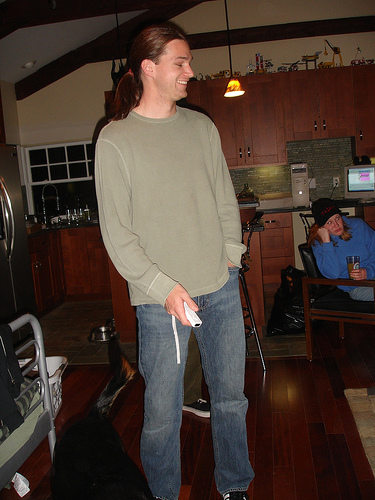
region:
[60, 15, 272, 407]
A man playing Wii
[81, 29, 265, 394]
A man holding a Wii controler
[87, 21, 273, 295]
A man wearing a green shirt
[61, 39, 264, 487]
A man wearing a jeans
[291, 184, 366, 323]
A person sitting in a chair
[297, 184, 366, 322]
A person in a blue shirt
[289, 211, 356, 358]
A person sitting in a black chair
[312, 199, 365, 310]
A person holding a cup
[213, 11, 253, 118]
A light hanging from the ceiling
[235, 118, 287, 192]
brown cabinets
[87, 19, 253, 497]
man holding a white video game controller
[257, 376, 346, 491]
dark hardwood floor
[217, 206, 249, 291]
man's hand in his pocket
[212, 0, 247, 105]
light with a small shade hanging from above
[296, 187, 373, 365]
woman sitting in a chair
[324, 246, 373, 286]
woman resting a drink on chair arm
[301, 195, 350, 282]
woman resting her head on her hand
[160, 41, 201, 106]
man smiling with his eyes closed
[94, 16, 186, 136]
man's brown hair pulled back into a low ponytail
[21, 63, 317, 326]
wooden cabinets and a window in the background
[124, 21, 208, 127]
person smiling with eyes closed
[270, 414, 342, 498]
brown floor beneath man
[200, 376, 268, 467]
long blue pants of man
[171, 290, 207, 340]
remote in man's hand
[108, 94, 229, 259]
long sleeve shirt of man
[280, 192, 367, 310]
woman sitting down in chair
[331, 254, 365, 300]
cup in woman's hand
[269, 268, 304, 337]
black bag behind woman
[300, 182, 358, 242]
black and red hat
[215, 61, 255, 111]
light hanging from ceiling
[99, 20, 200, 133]
person with a ponytail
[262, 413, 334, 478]
reddish brown floor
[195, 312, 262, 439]
blue pants on person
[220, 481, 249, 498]
black and white shoe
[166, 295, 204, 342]
white remote in person's hand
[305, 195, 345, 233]
red and black hat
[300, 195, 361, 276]
girl looking at something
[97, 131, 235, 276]
long sleeve shirt on person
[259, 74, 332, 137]
brown cabinets above ground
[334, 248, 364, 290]
cup in lady's hand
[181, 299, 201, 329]
white video game controller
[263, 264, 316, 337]
black trash bag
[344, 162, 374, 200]
white computer monitor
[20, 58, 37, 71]
kitchen light turned off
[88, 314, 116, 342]
empty dog food dish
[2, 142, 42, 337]
clean stainless steel fridge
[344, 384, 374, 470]
section of tan throw rug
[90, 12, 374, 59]
dark wooden beam across back wall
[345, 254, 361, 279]
clear glass with orange beverage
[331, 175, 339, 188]
outlet in back wall with one plug in use